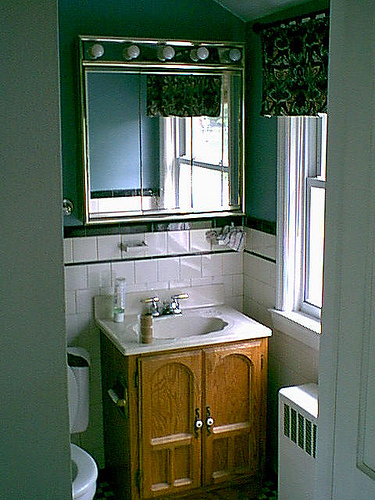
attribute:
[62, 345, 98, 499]
toilet — white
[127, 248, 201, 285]
tile — white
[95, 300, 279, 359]
sink — white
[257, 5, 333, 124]
valance — green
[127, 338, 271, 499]
cabinet — wooden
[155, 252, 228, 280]
tile — white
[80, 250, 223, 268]
tile — blue striped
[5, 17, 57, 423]
wall — green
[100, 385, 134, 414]
tube — empty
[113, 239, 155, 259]
dish — soap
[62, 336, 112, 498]
toilet — white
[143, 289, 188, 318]
faucet — silver, gold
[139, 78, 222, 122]
reflection — curtain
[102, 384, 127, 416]
holder — toilet paper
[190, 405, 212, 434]
knobs — cabinet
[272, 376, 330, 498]
heater — white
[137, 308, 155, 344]
roll — toilet paper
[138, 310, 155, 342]
roll — toilet paper, carboard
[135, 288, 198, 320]
handles — silver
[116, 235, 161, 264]
holder — soap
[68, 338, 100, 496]
toilet — white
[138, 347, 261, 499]
doors — sink cabinet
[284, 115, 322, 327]
bathroom window — closed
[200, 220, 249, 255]
washcloth — red, white, blue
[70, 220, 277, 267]
tile — black, white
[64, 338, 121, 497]
toilet — white